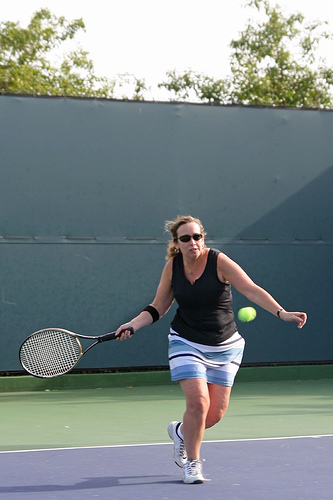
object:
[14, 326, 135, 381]
racket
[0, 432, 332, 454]
line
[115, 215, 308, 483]
woman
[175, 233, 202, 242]
glasses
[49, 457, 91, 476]
purple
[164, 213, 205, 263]
hair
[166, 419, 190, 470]
shoe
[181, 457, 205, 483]
shoe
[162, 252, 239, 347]
shirt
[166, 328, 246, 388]
skirt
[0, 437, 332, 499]
paint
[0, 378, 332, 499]
court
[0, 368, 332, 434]
purple paint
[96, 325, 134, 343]
black grip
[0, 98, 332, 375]
wall